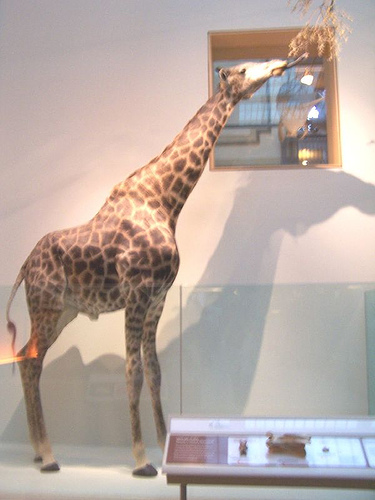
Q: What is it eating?
A: Leaves.